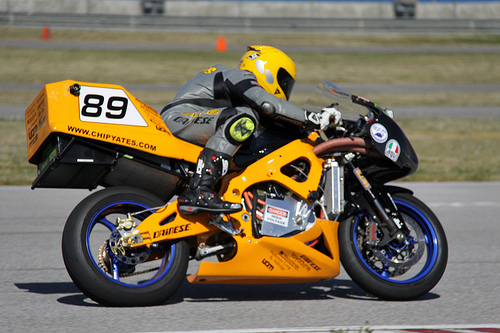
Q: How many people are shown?
A: One.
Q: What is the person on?
A: Motorcycle.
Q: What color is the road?
A: Gray.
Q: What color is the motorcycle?
A: Yellow.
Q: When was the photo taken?
A: Daytime.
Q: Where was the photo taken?
A: Track.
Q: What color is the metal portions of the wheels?
A: Blue.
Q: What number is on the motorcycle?
A: 89.